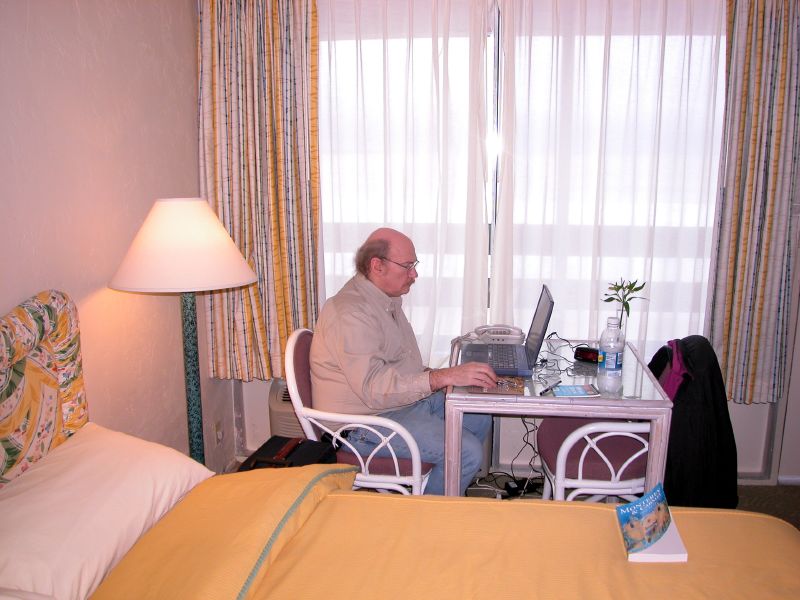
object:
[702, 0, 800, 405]
curtain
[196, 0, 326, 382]
curtain panel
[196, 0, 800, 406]
window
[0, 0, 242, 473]
wall